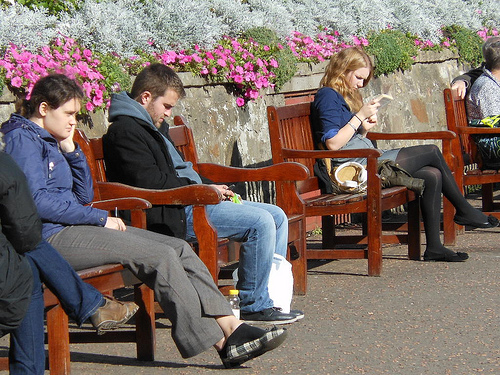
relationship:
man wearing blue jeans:
[108, 55, 313, 302] [184, 195, 292, 313]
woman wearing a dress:
[312, 27, 494, 272] [301, 86, 399, 179]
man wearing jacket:
[108, 55, 313, 302] [97, 90, 218, 237]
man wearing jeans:
[108, 55, 313, 302] [180, 198, 291, 311]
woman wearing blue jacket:
[3, 72, 288, 368] [2, 114, 128, 248]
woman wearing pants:
[3, 72, 288, 368] [38, 217, 242, 364]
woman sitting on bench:
[312, 27, 494, 272] [263, 90, 465, 275]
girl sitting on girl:
[307, 39, 498, 263] [2, 71, 289, 365]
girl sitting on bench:
[307, 39, 498, 263] [438, 84, 498, 222]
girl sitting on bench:
[307, 39, 498, 263] [258, 99, 460, 277]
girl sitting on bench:
[307, 39, 498, 263] [76, 113, 311, 298]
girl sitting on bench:
[307, 39, 498, 263] [38, 130, 156, 372]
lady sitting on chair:
[3, 71, 288, 368] [45, 127, 150, 374]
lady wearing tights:
[308, 47, 498, 265] [396, 144, 489, 259]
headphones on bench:
[332, 156, 369, 196] [264, 101, 455, 285]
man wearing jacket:
[108, 55, 313, 302] [98, 102, 199, 226]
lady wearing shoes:
[308, 47, 498, 265] [219, 318, 286, 366]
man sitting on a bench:
[108, 55, 313, 302] [76, 113, 311, 298]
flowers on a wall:
[1, 19, 498, 109] [0, 46, 483, 254]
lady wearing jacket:
[308, 47, 498, 265] [312, 86, 362, 154]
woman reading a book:
[312, 27, 494, 272] [364, 88, 397, 132]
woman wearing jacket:
[3, 72, 288, 368] [0, 149, 41, 337]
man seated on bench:
[108, 55, 313, 302] [76, 113, 311, 298]